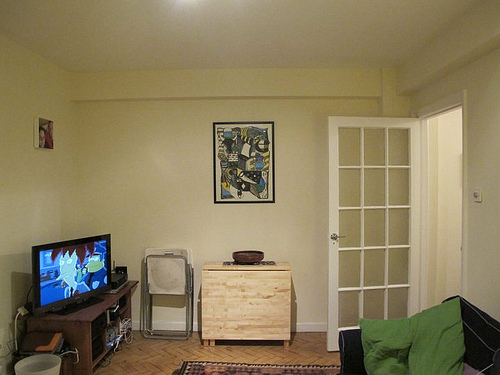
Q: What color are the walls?
A: White.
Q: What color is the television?
A: Black.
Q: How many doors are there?
A: One.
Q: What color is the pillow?
A: Green.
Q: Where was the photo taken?
A: In a living room.